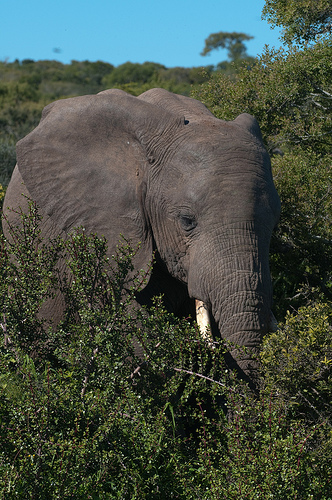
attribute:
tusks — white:
[194, 299, 279, 350]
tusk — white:
[191, 297, 218, 354]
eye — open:
[174, 207, 198, 231]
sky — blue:
[1, 0, 297, 56]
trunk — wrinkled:
[187, 229, 270, 379]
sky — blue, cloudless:
[54, 9, 200, 83]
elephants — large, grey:
[54, 105, 270, 372]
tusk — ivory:
[181, 289, 249, 346]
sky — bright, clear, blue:
[50, 0, 215, 77]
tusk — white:
[181, 289, 225, 351]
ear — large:
[13, 94, 174, 275]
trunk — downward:
[214, 270, 268, 388]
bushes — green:
[10, 49, 325, 496]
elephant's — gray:
[34, 172, 285, 390]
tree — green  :
[201, 31, 254, 67]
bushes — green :
[13, 237, 185, 491]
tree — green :
[262, 1, 330, 51]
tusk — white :
[194, 297, 217, 350]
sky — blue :
[0, 4, 324, 68]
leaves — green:
[72, 240, 134, 340]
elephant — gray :
[190, 252, 291, 390]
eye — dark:
[181, 213, 196, 229]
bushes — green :
[7, 215, 329, 496]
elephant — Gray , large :
[11, 82, 268, 374]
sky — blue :
[3, 1, 313, 74]